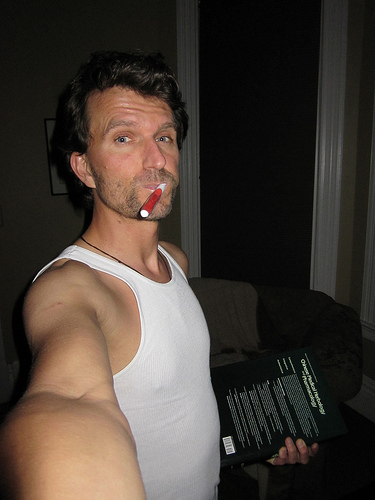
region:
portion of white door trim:
[318, 138, 341, 193]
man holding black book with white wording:
[212, 347, 327, 442]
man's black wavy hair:
[67, 52, 188, 97]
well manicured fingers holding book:
[276, 435, 319, 468]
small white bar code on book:
[223, 433, 239, 458]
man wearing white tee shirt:
[59, 239, 220, 442]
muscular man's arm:
[23, 286, 121, 498]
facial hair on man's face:
[127, 170, 180, 224]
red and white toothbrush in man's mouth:
[136, 173, 179, 224]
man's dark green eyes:
[109, 126, 195, 150]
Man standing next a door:
[8, 67, 247, 497]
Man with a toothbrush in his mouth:
[2, 68, 249, 497]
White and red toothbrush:
[133, 178, 174, 218]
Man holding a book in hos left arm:
[8, 61, 339, 498]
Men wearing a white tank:
[6, 68, 230, 498]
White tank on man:
[37, 234, 223, 498]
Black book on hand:
[214, 347, 338, 468]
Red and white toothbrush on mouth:
[136, 169, 177, 223]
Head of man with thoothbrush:
[59, 62, 198, 230]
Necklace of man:
[72, 232, 175, 288]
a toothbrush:
[139, 178, 168, 219]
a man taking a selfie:
[0, 43, 335, 498]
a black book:
[203, 342, 348, 475]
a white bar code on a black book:
[219, 435, 237, 458]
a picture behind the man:
[40, 114, 80, 199]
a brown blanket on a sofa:
[173, 268, 291, 385]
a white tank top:
[20, 242, 228, 498]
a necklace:
[73, 229, 178, 285]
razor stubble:
[87, 162, 180, 222]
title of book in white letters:
[295, 356, 328, 416]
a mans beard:
[102, 164, 194, 222]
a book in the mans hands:
[211, 330, 339, 484]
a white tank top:
[41, 236, 265, 496]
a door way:
[163, 4, 359, 284]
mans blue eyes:
[106, 126, 186, 151]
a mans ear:
[63, 148, 115, 190]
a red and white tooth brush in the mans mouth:
[134, 181, 179, 219]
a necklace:
[73, 233, 207, 289]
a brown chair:
[203, 266, 363, 387]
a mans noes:
[143, 136, 168, 176]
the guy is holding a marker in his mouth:
[104, 105, 190, 219]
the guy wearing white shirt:
[144, 314, 208, 439]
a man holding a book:
[243, 366, 319, 462]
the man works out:
[51, 307, 117, 433]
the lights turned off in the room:
[229, 111, 283, 243]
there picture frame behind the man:
[42, 113, 51, 145]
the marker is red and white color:
[146, 182, 163, 218]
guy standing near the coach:
[229, 322, 265, 353]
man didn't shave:
[97, 164, 129, 205]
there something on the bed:
[268, 293, 293, 320]